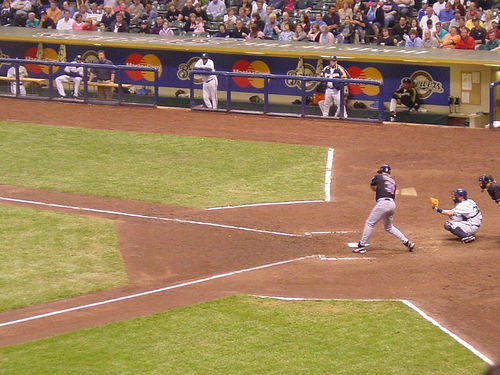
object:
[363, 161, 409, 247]
batter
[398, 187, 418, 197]
bat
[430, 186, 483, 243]
catcher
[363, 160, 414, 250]
batter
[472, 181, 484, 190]
referee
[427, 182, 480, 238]
catcher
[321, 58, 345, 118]
player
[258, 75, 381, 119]
railing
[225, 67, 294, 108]
railing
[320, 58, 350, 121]
player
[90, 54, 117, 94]
man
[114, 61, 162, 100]
railing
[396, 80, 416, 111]
player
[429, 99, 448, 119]
bench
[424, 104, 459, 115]
bench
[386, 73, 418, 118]
player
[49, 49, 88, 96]
player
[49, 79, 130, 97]
bench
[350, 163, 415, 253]
player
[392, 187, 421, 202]
bat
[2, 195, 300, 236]
line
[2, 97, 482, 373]
playing field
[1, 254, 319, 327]
line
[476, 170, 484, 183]
umpire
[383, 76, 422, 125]
player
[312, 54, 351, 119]
player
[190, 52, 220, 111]
player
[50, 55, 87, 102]
player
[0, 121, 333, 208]
grass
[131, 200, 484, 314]
field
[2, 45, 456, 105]
wall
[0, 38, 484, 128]
dugout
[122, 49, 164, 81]
logo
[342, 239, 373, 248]
home plate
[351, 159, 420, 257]
batter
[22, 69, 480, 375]
game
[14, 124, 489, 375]
game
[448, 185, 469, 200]
purple hat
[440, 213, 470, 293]
player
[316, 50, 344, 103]
player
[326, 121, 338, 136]
purple hat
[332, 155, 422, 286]
person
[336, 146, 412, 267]
baseball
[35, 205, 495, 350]
field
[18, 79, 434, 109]
baseball players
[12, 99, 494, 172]
dugout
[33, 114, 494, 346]
field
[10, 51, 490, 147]
crowd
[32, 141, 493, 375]
game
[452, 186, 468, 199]
helmet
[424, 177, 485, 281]
man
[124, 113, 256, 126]
rail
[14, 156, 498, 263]
field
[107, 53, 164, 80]
mastercard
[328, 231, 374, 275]
home plate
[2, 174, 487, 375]
field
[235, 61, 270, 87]
sign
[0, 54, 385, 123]
fence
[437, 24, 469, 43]
person